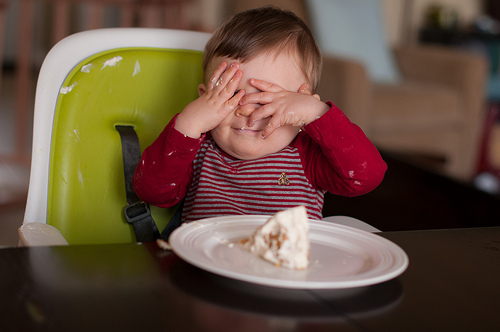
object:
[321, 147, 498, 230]
foor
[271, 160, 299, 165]
red stripe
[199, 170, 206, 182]
stripe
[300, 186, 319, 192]
stripe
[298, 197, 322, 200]
stripe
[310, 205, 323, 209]
stripe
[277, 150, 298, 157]
strip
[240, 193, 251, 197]
stripe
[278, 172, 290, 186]
bear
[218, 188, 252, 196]
red strip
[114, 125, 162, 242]
black strap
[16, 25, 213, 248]
highchair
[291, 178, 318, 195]
red strip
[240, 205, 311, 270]
food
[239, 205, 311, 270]
cake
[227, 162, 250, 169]
stripe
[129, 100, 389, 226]
shirt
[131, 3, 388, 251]
baby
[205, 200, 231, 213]
stripes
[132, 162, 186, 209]
elbow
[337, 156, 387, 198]
elbow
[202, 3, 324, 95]
hair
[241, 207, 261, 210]
red stripe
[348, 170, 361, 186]
food stain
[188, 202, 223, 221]
red stripe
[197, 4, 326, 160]
head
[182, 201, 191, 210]
stripe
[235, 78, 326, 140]
baby's hand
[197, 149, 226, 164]
red stripe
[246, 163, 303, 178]
red stripe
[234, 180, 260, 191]
red stripe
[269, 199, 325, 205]
red stripe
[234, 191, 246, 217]
red stripe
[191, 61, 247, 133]
hands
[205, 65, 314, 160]
face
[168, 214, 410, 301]
plate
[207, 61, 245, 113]
fingers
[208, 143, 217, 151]
stripe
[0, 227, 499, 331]
table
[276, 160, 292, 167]
stripe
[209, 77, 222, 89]
food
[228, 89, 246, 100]
eyes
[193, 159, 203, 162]
strip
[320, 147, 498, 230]
floor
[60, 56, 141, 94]
food